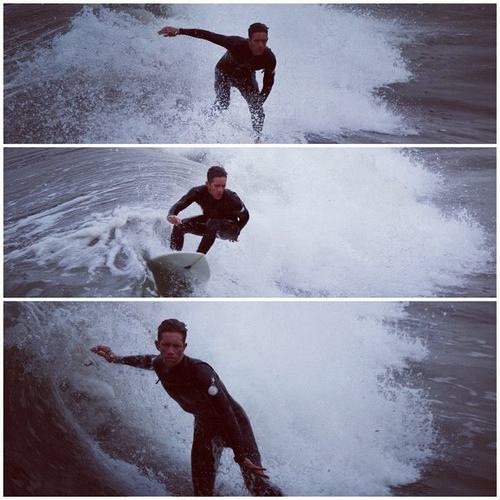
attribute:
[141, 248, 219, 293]
surfboard — white, tilted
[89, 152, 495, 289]
wave — rolling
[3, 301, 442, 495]
wave — white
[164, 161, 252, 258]
man — surfing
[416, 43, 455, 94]
water — white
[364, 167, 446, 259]
wave — crashing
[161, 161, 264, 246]
man — leaning to left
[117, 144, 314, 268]
man — surfing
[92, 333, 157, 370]
arm — extended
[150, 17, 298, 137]
man — leaning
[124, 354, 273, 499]
suit — black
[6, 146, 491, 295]
wave — rolling